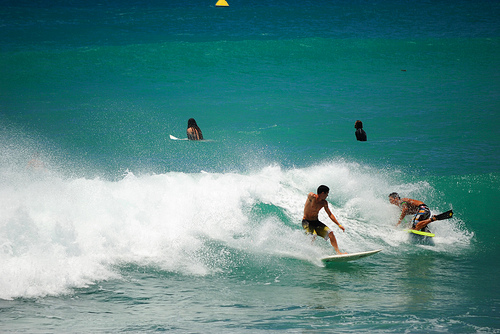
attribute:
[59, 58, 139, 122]
ocean — water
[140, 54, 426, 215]
scene — day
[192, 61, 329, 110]
water — white, green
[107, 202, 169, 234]
white — wave, surfboard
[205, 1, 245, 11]
yellow — object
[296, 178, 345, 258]
man — surfing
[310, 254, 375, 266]
surfboard — used, white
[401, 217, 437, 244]
green and yellow — surfboard